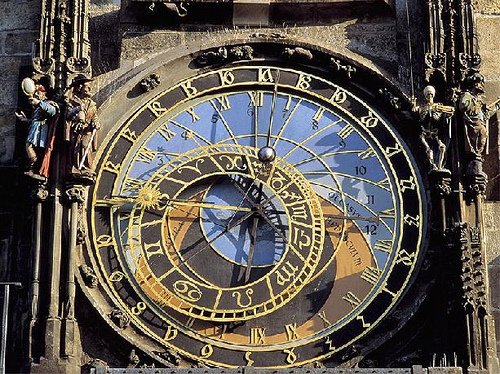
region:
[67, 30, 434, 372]
and astronomical clock on wall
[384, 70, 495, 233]
statues on right side astronomical clock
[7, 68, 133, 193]
statues on left side astronomical clock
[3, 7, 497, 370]
wall is color gray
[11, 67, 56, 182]
statue with blue and red clothes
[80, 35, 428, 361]
astronomical clock with blue and brown background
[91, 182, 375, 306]
handles of astronomical clock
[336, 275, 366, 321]
number XI on astronomical clock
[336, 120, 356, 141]
number III on astronomical clock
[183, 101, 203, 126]
number X on astronomical clock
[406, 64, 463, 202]
a carved skeleton on clock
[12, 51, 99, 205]
the sculptures are painted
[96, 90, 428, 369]
a fancy european clock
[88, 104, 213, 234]
the numbers are gold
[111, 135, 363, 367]
the clock dial for astrology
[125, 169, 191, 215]
the symbol of the sun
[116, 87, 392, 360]
the clock dial is blue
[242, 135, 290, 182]
the symbol of the moon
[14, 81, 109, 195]
two sculptures on the side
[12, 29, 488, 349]
a medieval clock face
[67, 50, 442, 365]
an old astrological clock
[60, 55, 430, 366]
astrological clock with signs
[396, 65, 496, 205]
two statues on the wall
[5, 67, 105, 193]
two statues on left side of astrological clock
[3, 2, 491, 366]
an astrological clock over a gray wall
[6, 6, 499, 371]
wall of building is gray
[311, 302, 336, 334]
number X on clock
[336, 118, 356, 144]
number II on clock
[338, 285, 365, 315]
number XI on clock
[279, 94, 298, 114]
number I on clock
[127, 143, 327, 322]
there is an indicator for the signs of the zodiac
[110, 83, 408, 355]
this looks like a 24-hour clock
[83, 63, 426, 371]
it is next to impossible to tell the time on this weird clock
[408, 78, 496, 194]
elaborate carved figures next to the clock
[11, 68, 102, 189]
elaborate carved figures next to the clock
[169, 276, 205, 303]
this is the astrological sign for Cancer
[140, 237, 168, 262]
this is the astrological sign for Gemini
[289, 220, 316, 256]
this is the astrological sign for Libra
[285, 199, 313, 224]
this is the astrological sign for Scorpio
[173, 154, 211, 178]
this is the astrological sign for Aries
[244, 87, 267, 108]
yellow roman numeral on clock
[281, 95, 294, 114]
yellow roman numeral on clock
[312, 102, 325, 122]
yellow roman numeral on clock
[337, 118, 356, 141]
yellow roman numeral on clock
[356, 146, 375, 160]
yellow roman numeral on clock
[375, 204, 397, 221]
yellow roman numeral on clock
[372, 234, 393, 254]
yellow roman numeral on clock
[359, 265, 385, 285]
yellow roman numeral on clock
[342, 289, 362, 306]
yellow roman numeral on clock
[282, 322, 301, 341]
yellow roman numeral on clock